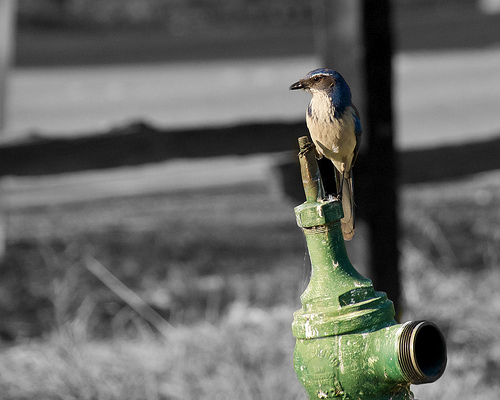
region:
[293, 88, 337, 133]
prt of a chest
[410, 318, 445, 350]
part of a spasce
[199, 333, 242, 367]
part of a ground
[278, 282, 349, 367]
edge of a post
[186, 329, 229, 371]
part of a ground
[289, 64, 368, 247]
blue bird sitting on perch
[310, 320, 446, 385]
opening of fire hydrant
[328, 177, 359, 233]
tail of blue bird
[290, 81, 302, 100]
beak of blue bird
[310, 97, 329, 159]
chest of blue bird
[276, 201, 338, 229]
to of fire hydrant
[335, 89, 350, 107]
neck of the blue bird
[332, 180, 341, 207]
small legs of blue bird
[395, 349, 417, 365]
ridges of fire hydrant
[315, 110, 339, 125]
feathers on blue bird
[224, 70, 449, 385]
a bird on an old hydrant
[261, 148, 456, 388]
the hydrant is green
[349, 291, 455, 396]
this is a hose connection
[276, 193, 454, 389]
this hydrant is old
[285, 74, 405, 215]
this is a blue bird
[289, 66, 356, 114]
the bird's head is blue and white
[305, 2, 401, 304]
a pole behind the bird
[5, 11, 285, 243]
a curb along the street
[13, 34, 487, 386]
the background is black and white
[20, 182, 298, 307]
this is grass in the shot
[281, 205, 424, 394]
a fire hydrant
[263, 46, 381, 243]
this is a bird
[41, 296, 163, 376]
grass on the ground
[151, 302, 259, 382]
grass on the ground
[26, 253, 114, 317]
grass on the ground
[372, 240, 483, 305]
grass on the ground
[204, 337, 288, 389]
grass on the ground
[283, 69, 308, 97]
the beak of a bird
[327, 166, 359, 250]
the tail of a bird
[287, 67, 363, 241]
bully blue jay sitting on a water well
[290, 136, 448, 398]
age green water well in definite need of a paint job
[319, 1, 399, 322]
wooden fence post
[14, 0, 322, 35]
tree line in the background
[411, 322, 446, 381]
small opening in the water well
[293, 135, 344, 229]
nozzle of the water well that needs a wrench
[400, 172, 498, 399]
area of grass that's covered in snow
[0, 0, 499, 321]
blurry wooden fence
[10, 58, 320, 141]
white area in the back ground that looks like maybe a frozen pond or something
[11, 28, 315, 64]
wooden horizontal fence piece